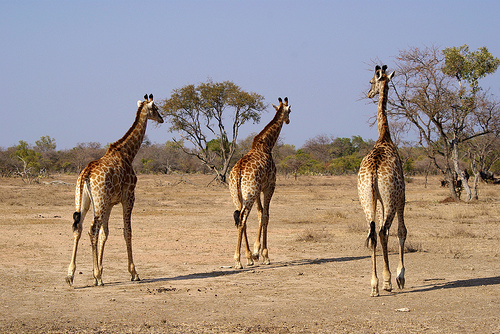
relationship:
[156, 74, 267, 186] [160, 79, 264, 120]
tree with leaves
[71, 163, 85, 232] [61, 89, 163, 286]
tail on giraffe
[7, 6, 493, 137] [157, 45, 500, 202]
sky over trees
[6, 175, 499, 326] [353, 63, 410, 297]
dirt under giraffe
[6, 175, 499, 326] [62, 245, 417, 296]
dirt under feet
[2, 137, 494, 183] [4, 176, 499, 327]
bushes behind field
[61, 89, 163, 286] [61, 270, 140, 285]
giraffe four feet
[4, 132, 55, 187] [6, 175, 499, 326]
shrub on dirt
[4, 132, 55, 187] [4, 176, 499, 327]
shrub on field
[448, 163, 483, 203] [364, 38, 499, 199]
base of tree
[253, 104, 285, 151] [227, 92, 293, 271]
mane on giraffe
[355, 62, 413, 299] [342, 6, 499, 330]
giraffe on right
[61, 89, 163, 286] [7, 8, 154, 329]
giraffe on left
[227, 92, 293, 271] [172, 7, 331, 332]
giraffe in middle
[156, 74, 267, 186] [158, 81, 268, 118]
tree with green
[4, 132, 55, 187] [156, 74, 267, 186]
shrub like tree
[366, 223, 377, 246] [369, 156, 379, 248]
hair on tail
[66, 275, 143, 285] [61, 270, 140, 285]
hooves on feet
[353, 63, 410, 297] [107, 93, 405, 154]
giraffe with necks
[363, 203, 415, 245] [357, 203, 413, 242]
markings across thighs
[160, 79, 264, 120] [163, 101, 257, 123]
leaves on ends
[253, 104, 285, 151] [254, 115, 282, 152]
mane running down neck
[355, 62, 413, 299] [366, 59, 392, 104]
giraffe turned head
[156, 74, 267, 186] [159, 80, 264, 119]
tree in fan shape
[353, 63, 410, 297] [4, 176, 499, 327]
giraffe in field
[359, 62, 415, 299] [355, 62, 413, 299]
brown walking giraffe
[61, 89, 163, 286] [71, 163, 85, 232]
giraffe with bushy tail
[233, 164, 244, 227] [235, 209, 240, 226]
tail with black end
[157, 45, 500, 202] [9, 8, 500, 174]
trees in background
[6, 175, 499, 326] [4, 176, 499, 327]
dirt bush field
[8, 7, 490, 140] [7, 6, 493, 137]
blue cloudless sky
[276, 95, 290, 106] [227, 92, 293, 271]
horns on giraffe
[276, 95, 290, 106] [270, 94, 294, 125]
horns on head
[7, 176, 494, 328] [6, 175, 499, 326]
brown surface ground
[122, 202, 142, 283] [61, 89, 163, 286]
leg of giraffe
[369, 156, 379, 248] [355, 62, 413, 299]
tail on giraffe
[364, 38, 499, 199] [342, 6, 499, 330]
tree on right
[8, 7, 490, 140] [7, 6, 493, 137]
blue grayish sky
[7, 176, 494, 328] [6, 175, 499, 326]
brown dry ground